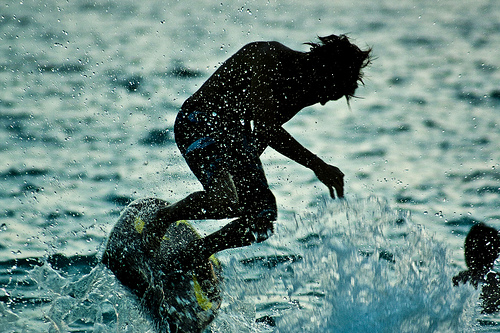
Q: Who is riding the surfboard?
A: The man in the photo.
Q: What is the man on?
A: A surfboard.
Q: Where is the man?
A: In the water.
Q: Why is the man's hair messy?
A: He's surfing.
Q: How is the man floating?
A: He's standing on a surfboard.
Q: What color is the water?
A: Blue.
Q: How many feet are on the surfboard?
A: Two.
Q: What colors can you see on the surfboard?
A: Yellow and black.